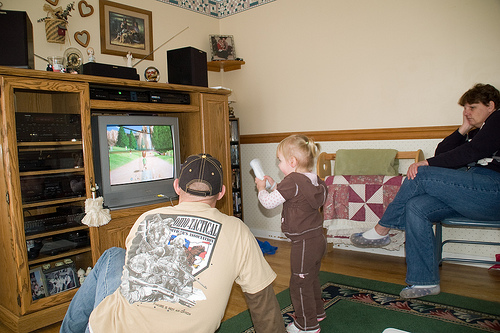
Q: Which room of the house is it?
A: It is a living room.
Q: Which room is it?
A: It is a living room.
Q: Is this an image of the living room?
A: Yes, it is showing the living room.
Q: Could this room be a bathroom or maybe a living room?
A: It is a living room.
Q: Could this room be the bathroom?
A: No, it is the living room.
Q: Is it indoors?
A: Yes, it is indoors.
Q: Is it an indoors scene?
A: Yes, it is indoors.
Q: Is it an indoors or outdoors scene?
A: It is indoors.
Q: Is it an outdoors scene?
A: No, it is indoors.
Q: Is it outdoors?
A: No, it is indoors.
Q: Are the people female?
A: No, they are both male and female.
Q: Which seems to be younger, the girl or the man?
A: The girl is younger than the man.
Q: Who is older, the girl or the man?
A: The man is older than the girl.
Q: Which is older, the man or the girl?
A: The man is older than the girl.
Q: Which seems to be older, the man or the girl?
A: The man is older than the girl.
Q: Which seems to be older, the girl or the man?
A: The man is older than the girl.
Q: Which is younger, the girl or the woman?
A: The girl is younger than the woman.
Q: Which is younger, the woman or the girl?
A: The girl is younger than the woman.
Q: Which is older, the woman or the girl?
A: The woman is older than the girl.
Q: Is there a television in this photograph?
A: Yes, there is a television.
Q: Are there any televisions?
A: Yes, there is a television.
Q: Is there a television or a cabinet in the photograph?
A: Yes, there is a television.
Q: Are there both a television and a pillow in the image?
A: No, there is a television but no pillows.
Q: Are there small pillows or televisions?
A: Yes, there is a small television.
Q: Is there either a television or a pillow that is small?
A: Yes, the television is small.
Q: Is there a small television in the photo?
A: Yes, there is a small television.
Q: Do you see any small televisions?
A: Yes, there is a small television.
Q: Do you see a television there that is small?
A: Yes, there is a television that is small.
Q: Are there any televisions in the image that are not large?
A: Yes, there is a small television.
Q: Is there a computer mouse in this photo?
A: No, there are no computer mice.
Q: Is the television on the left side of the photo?
A: Yes, the television is on the left of the image.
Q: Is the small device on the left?
A: Yes, the television is on the left of the image.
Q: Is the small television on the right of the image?
A: No, the TV is on the left of the image.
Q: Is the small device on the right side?
A: No, the TV is on the left of the image.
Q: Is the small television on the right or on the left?
A: The TV is on the left of the image.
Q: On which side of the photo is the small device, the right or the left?
A: The TV is on the left of the image.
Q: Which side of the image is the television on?
A: The television is on the left of the image.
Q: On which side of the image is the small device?
A: The television is on the left of the image.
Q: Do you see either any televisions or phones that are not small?
A: No, there is a television but it is small.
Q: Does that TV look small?
A: Yes, the TV is small.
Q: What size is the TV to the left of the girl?
A: The television is small.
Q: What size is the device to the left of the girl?
A: The television is small.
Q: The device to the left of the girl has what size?
A: The television is small.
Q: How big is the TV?
A: The TV is small.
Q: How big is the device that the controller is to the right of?
A: The TV is small.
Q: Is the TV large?
A: No, the TV is small.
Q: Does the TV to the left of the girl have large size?
A: No, the TV is small.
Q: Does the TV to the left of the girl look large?
A: No, the TV is small.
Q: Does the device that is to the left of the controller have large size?
A: No, the TV is small.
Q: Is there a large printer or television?
A: No, there is a television but it is small.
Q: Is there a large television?
A: No, there is a television but it is small.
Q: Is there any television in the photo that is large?
A: No, there is a television but it is small.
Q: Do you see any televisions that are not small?
A: No, there is a television but it is small.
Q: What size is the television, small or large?
A: The television is small.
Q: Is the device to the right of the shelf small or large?
A: The television is small.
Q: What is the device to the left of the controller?
A: The device is a television.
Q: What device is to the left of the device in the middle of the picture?
A: The device is a television.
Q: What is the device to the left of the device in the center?
A: The device is a television.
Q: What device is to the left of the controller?
A: The device is a television.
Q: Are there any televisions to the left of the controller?
A: Yes, there is a television to the left of the controller.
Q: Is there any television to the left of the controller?
A: Yes, there is a television to the left of the controller.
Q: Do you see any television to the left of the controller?
A: Yes, there is a television to the left of the controller.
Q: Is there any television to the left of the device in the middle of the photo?
A: Yes, there is a television to the left of the controller.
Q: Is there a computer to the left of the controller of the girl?
A: No, there is a television to the left of the controller.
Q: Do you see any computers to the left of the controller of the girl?
A: No, there is a television to the left of the controller.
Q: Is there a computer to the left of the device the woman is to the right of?
A: No, there is a television to the left of the controller.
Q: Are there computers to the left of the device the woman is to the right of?
A: No, there is a television to the left of the controller.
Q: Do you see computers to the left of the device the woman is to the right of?
A: No, there is a television to the left of the controller.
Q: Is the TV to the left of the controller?
A: Yes, the TV is to the left of the controller.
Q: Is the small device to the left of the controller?
A: Yes, the TV is to the left of the controller.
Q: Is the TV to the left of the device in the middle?
A: Yes, the TV is to the left of the controller.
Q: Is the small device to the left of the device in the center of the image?
A: Yes, the TV is to the left of the controller.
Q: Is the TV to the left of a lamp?
A: No, the TV is to the left of the controller.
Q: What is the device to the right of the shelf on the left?
A: The device is a television.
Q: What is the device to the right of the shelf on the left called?
A: The device is a television.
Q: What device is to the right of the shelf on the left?
A: The device is a television.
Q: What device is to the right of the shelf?
A: The device is a television.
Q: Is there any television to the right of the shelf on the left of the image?
A: Yes, there is a television to the right of the shelf.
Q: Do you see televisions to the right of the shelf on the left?
A: Yes, there is a television to the right of the shelf.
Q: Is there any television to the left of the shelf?
A: No, the television is to the right of the shelf.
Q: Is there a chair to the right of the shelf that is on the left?
A: No, there is a television to the right of the shelf.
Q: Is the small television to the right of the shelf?
A: Yes, the TV is to the right of the shelf.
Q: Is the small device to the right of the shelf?
A: Yes, the TV is to the right of the shelf.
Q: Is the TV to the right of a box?
A: No, the TV is to the right of the shelf.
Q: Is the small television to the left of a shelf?
A: No, the television is to the right of a shelf.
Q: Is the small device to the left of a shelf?
A: No, the television is to the right of a shelf.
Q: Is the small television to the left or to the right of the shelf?
A: The television is to the right of the shelf.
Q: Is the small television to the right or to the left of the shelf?
A: The television is to the right of the shelf.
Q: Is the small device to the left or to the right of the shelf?
A: The television is to the right of the shelf.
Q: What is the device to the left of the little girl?
A: The device is a television.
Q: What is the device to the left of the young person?
A: The device is a television.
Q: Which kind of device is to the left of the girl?
A: The device is a television.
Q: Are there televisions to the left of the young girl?
A: Yes, there is a television to the left of the girl.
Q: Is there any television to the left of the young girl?
A: Yes, there is a television to the left of the girl.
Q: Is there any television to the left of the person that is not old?
A: Yes, there is a television to the left of the girl.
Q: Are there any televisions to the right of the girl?
A: No, the television is to the left of the girl.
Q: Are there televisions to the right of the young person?
A: No, the television is to the left of the girl.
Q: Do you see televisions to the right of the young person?
A: No, the television is to the left of the girl.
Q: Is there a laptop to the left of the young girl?
A: No, there is a television to the left of the girl.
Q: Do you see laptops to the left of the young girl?
A: No, there is a television to the left of the girl.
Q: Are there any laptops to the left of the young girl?
A: No, there is a television to the left of the girl.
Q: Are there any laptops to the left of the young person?
A: No, there is a television to the left of the girl.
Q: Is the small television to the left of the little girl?
A: Yes, the TV is to the left of the girl.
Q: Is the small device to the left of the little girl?
A: Yes, the TV is to the left of the girl.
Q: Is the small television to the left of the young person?
A: Yes, the TV is to the left of the girl.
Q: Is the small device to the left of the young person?
A: Yes, the TV is to the left of the girl.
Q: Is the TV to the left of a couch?
A: No, the TV is to the left of the girl.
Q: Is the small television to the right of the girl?
A: No, the television is to the left of the girl.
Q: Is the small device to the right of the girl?
A: No, the television is to the left of the girl.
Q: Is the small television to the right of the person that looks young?
A: No, the television is to the left of the girl.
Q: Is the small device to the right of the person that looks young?
A: No, the television is to the left of the girl.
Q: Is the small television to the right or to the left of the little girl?
A: The television is to the left of the girl.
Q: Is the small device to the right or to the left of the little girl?
A: The television is to the left of the girl.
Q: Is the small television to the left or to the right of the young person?
A: The television is to the left of the girl.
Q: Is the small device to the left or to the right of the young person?
A: The television is to the left of the girl.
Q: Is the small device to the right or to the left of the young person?
A: The television is to the left of the girl.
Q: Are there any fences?
A: No, there are no fences.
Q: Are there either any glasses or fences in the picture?
A: No, there are no fences or glasses.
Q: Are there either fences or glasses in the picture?
A: No, there are no fences or glasses.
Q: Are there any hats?
A: Yes, there is a hat.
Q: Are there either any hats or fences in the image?
A: Yes, there is a hat.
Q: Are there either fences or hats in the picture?
A: Yes, there is a hat.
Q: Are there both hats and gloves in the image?
A: No, there is a hat but no gloves.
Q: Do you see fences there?
A: No, there are no fences.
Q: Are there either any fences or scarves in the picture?
A: No, there are no fences or scarves.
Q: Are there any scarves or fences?
A: No, there are no fences or scarves.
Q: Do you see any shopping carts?
A: No, there are no shopping carts.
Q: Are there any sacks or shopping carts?
A: No, there are no shopping carts or sacks.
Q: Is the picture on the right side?
A: No, the picture is on the left of the image.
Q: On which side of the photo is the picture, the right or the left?
A: The picture is on the left of the image.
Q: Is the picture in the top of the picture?
A: Yes, the picture is in the top of the image.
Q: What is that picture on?
A: The picture is on the wall.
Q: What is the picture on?
A: The picture is on the wall.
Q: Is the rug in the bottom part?
A: Yes, the rug is in the bottom of the image.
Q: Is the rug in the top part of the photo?
A: No, the rug is in the bottom of the image.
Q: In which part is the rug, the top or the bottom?
A: The rug is in the bottom of the image.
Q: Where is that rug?
A: The rug is on the floor.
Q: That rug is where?
A: The rug is on the floor.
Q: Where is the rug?
A: The rug is on the floor.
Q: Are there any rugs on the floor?
A: Yes, there is a rug on the floor.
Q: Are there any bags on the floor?
A: No, there is a rug on the floor.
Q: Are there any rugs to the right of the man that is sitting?
A: Yes, there is a rug to the right of the man.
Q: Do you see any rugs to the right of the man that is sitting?
A: Yes, there is a rug to the right of the man.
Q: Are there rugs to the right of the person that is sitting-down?
A: Yes, there is a rug to the right of the man.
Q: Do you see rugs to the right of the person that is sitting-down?
A: Yes, there is a rug to the right of the man.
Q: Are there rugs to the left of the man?
A: No, the rug is to the right of the man.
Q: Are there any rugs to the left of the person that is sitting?
A: No, the rug is to the right of the man.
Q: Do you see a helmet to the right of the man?
A: No, there is a rug to the right of the man.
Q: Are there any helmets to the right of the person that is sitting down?
A: No, there is a rug to the right of the man.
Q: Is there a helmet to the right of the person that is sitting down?
A: No, there is a rug to the right of the man.